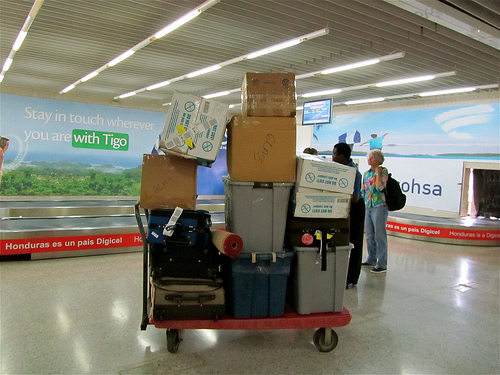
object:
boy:
[360, 132, 390, 150]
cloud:
[431, 104, 495, 143]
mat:
[209, 228, 244, 257]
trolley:
[134, 200, 351, 352]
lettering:
[73, 132, 128, 149]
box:
[140, 154, 197, 210]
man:
[332, 142, 365, 291]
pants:
[350, 197, 367, 289]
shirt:
[340, 161, 363, 197]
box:
[158, 90, 229, 168]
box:
[228, 116, 297, 184]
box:
[241, 72, 296, 117]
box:
[293, 154, 357, 218]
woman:
[360, 149, 389, 274]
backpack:
[385, 173, 407, 211]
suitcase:
[147, 207, 211, 245]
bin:
[224, 176, 294, 253]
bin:
[231, 252, 291, 319]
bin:
[296, 244, 352, 315]